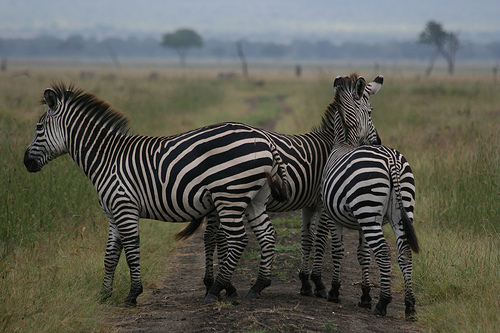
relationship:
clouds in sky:
[0, 16, 482, 43] [3, 0, 498, 40]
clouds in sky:
[0, 16, 482, 43] [3, 0, 499, 52]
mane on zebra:
[55, 83, 119, 127] [21, 87, 293, 274]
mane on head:
[55, 83, 119, 127] [17, 93, 99, 170]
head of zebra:
[17, 93, 99, 170] [21, 87, 293, 274]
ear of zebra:
[44, 90, 60, 111] [24, 74, 280, 311]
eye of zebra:
[30, 118, 44, 135] [12, 80, 269, 330]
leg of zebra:
[113, 214, 145, 305] [13, 72, 278, 299]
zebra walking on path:
[13, 72, 278, 299] [127, 109, 424, 329]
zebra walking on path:
[173, 70, 388, 295] [127, 109, 424, 329]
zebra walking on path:
[320, 72, 420, 319] [127, 109, 424, 329]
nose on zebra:
[22, 148, 43, 174] [11, 87, 294, 296]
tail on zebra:
[395, 206, 425, 255] [24, 74, 280, 311]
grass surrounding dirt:
[3, 202, 153, 331] [141, 226, 395, 330]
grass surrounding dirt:
[3, 74, 500, 331] [141, 226, 395, 330]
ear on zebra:
[43, 88, 59, 111] [24, 74, 280, 311]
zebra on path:
[320, 72, 420, 319] [136, 83, 408, 329]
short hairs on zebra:
[65, 82, 140, 142] [19, 66, 293, 298]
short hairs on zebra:
[331, 88, 357, 154] [327, 62, 440, 326]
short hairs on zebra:
[320, 95, 337, 136] [245, 104, 463, 226]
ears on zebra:
[322, 56, 390, 100] [24, 74, 280, 311]